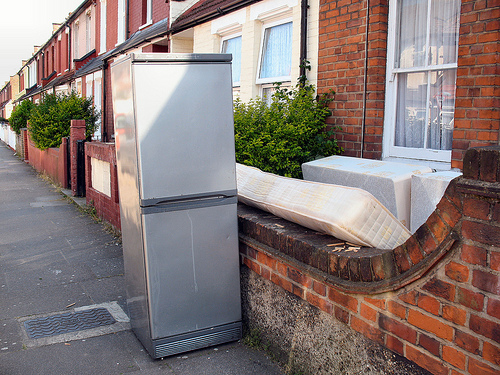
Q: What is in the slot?
A: Mattresses.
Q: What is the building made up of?
A: Brick.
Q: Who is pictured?
A: No one.